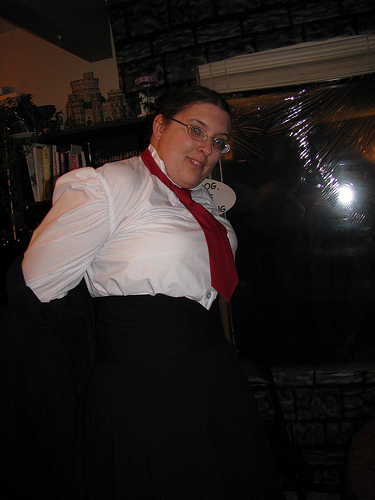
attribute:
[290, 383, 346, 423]
brick — on person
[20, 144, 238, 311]
shirt — on woman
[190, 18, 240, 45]
brick — dark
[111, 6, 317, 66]
dark brick — on wall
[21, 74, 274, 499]
lady — on wall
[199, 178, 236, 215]
poster — white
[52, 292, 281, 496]
skirt — black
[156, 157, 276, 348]
tie — maroon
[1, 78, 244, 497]
lady — on wall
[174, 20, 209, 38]
brick — on wall